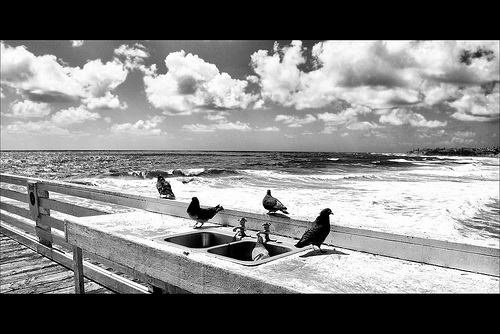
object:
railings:
[2, 170, 50, 256]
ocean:
[0, 149, 499, 249]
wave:
[107, 168, 236, 180]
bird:
[155, 173, 176, 200]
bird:
[186, 196, 224, 230]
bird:
[261, 187, 292, 216]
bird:
[294, 208, 335, 252]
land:
[409, 145, 498, 158]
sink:
[164, 231, 243, 250]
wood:
[64, 210, 500, 294]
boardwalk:
[2, 173, 140, 295]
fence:
[0, 171, 499, 295]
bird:
[250, 235, 269, 262]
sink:
[205, 241, 293, 263]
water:
[0, 149, 499, 294]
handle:
[261, 222, 272, 227]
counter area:
[62, 210, 498, 293]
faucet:
[256, 221, 271, 243]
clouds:
[0, 42, 36, 83]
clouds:
[454, 38, 497, 61]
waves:
[234, 167, 373, 181]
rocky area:
[408, 144, 500, 159]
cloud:
[140, 48, 262, 116]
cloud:
[204, 114, 226, 123]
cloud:
[346, 120, 386, 130]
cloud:
[379, 106, 449, 129]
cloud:
[50, 103, 103, 126]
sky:
[0, 40, 499, 151]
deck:
[1, 234, 116, 294]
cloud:
[434, 62, 497, 97]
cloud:
[333, 85, 423, 110]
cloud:
[327, 55, 402, 90]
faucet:
[232, 217, 247, 234]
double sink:
[150, 228, 310, 266]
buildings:
[406, 147, 420, 155]